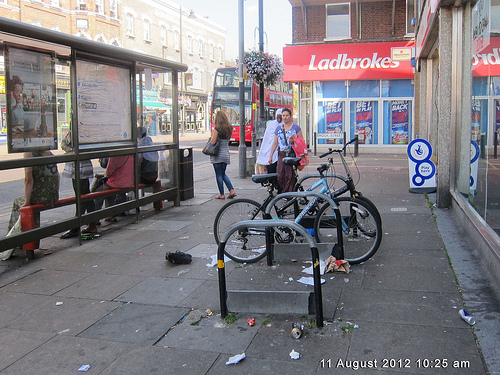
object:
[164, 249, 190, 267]
trash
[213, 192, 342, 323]
bicycle rack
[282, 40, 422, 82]
awning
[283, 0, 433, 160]
store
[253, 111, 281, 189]
people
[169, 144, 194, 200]
trash can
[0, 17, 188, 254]
bus stop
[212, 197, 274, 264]
wheel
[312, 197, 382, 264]
wheel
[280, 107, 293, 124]
head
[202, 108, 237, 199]
woman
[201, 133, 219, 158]
bag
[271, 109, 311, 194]
woman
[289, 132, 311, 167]
sweater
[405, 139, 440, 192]
display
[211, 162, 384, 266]
bicycle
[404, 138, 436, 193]
sign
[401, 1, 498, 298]
building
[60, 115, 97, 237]
person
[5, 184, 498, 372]
ground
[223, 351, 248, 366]
trash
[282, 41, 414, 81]
sign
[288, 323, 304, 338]
can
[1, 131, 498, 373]
concrete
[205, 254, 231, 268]
paper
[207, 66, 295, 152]
bus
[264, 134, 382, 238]
bicycle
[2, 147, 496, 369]
sidewalk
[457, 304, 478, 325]
can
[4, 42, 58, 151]
advertisement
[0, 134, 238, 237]
road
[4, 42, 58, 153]
sign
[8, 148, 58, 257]
person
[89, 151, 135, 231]
person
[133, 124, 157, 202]
person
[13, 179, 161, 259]
bench